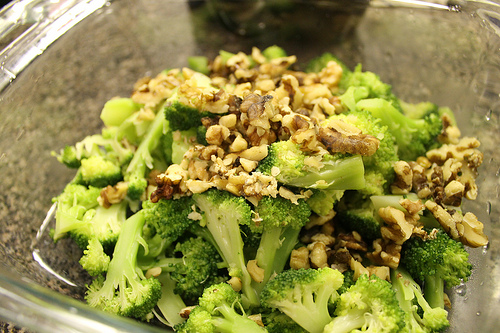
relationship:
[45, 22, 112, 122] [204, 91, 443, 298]
bowl of broccoli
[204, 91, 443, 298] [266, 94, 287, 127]
broccoli and nut